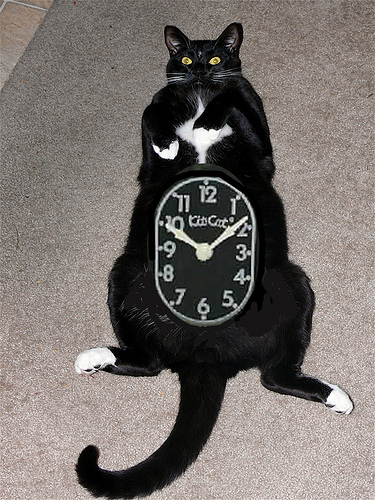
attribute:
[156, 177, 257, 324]
clock — white, oval, black, realistic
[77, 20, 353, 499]
cat — white, big, black, fake, clock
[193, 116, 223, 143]
paw — white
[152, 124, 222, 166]
paws — white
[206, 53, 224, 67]
eye — yellow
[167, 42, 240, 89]
face — black